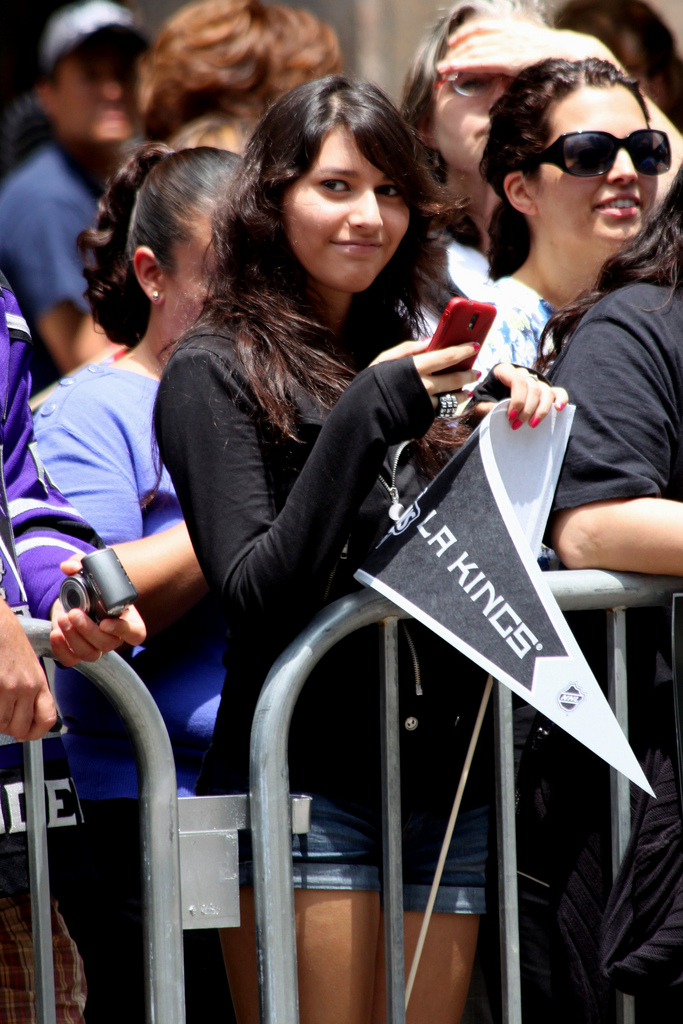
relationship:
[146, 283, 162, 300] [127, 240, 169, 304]
earring worn on ear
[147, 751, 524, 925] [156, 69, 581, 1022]
shorts on woman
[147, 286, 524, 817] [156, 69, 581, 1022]
shirt on woman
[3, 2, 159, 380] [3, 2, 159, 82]
man wearing hat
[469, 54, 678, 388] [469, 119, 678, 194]
woman wearing sunglasses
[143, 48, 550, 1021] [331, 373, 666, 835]
girl holding banner